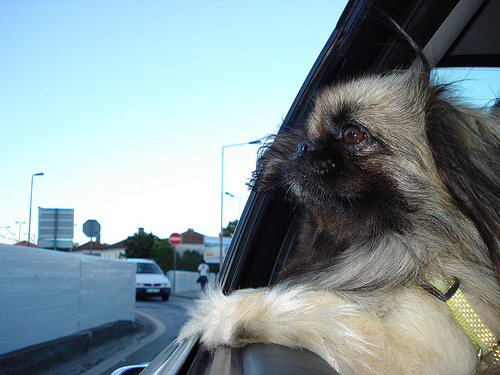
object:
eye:
[337, 123, 369, 146]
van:
[124, 257, 171, 302]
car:
[107, 0, 499, 374]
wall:
[0, 243, 136, 356]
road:
[33, 293, 196, 375]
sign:
[167, 232, 184, 247]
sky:
[0, 0, 499, 250]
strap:
[412, 266, 499, 366]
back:
[377, 242, 499, 374]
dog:
[175, 15, 499, 374]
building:
[0, 243, 136, 374]